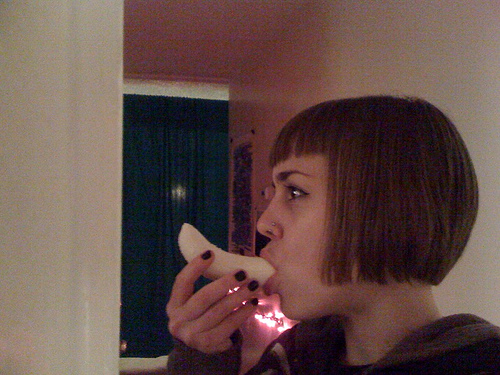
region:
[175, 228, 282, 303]
a woman eating banana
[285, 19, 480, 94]
white color wall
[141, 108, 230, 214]
curtains hanging in the window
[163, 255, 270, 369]
hand of the woman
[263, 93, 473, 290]
woman haircut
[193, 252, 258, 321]
brown color nail polish in her nail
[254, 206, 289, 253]
nose of the woman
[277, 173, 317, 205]
eyes of the woman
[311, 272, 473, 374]
neck of the woman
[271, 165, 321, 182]
eyebrow of the woman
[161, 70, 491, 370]
woman has short hair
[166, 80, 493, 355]
hair is color red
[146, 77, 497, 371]
woman is eating a banana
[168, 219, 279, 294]
the banana is peeled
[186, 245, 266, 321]
fingers with nail polish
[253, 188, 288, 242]
the nose is percing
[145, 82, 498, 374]
woman wears a long sleeve with hood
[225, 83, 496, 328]
woman has bangs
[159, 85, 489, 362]
pink light behind woman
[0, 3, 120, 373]
a white wall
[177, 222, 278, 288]
a banana in a woman's mouth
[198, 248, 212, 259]
a black painted nail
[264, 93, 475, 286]
a short bobcut on a woman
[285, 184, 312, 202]
the ye of a woman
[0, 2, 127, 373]
a white wall in front of a woman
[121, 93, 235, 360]
a blue curtain hanging in a doorway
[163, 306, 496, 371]
a sweatshirt on a woman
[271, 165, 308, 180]
the brown eyebrow of a woman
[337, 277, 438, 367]
the neck of a woman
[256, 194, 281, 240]
the nose of a woman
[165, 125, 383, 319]
a woman eating a banana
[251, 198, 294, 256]
the nose of a woman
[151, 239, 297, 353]
the hand of a woman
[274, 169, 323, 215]
the eye of a woman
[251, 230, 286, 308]
the lips on a woman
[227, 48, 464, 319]
the hair of a woman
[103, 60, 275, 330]
curtains on a window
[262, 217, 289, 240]
a nose ring in a woman nose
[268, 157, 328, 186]
the eyebrow of a woman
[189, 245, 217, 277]
the fingernail of a woman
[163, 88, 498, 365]
woman eating a banana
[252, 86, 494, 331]
woman with short pixie hair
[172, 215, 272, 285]
banana in the hand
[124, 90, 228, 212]
green curtain covering the window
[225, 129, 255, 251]
decoration on the wall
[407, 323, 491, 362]
part of the hoodie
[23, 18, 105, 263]
white wall in front of the woman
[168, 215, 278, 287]
banana in the womans mouth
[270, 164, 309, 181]
eyebrow on the face of the woman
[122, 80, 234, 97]
top of the window